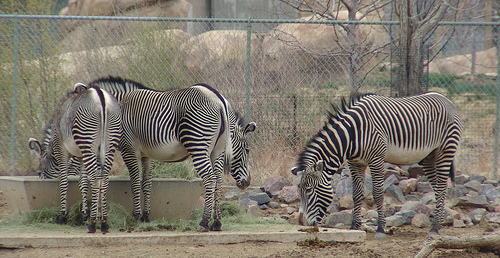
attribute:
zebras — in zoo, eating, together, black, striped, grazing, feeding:
[50, 82, 232, 241]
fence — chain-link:
[11, 22, 482, 78]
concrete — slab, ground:
[5, 230, 372, 244]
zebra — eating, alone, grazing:
[290, 81, 454, 236]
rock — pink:
[175, 35, 276, 103]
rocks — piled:
[53, 40, 383, 76]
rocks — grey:
[302, 157, 497, 211]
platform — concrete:
[5, 223, 394, 252]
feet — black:
[196, 213, 228, 232]